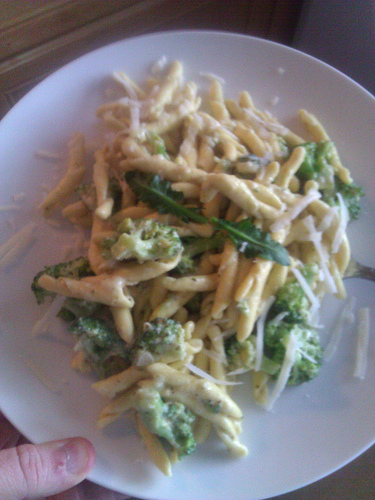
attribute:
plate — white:
[0, 31, 373, 499]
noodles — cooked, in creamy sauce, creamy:
[41, 64, 347, 325]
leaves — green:
[126, 171, 289, 263]